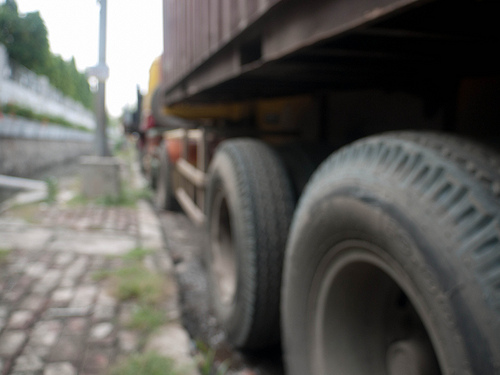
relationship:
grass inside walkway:
[0, 146, 196, 375] [3, 148, 199, 375]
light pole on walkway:
[92, 1, 107, 156] [5, 137, 200, 374]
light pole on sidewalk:
[92, 1, 107, 156] [0, 113, 185, 373]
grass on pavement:
[0, 146, 196, 375] [2, 143, 198, 373]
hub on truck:
[213, 208, 238, 308] [191, 136, 292, 356]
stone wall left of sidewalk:
[0, 59, 96, 174] [20, 165, 100, 297]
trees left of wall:
[0, 6, 94, 108] [11, 77, 102, 180]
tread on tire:
[298, 133, 499, 232] [281, 135, 498, 369]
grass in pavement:
[110, 246, 175, 343] [0, 146, 247, 373]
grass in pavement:
[0, 146, 196, 375] [0, 146, 247, 373]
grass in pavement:
[0, 146, 196, 375] [2, 119, 212, 370]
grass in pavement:
[0, 146, 196, 375] [9, 125, 221, 373]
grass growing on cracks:
[0, 146, 196, 375] [48, 248, 88, 310]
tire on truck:
[281, 135, 498, 369] [160, 2, 496, 370]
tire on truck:
[199, 134, 298, 365] [160, 2, 496, 370]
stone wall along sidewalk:
[0, 59, 96, 174] [3, 139, 203, 374]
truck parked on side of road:
[160, 2, 496, 370] [125, 152, 297, 374]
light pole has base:
[92, 1, 107, 156] [72, 140, 133, 220]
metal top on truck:
[157, 2, 349, 112] [160, 2, 496, 370]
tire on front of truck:
[281, 135, 498, 369] [159, 7, 496, 137]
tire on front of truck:
[199, 134, 298, 365] [159, 7, 496, 137]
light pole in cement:
[92, 1, 115, 156] [2, 116, 195, 373]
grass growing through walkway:
[0, 146, 196, 375] [3, 148, 199, 375]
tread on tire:
[298, 116, 498, 283] [228, 122, 498, 334]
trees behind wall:
[5, 2, 97, 97] [0, 45, 98, 214]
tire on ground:
[199, 134, 298, 365] [2, 103, 240, 370]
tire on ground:
[281, 135, 498, 375] [2, 103, 240, 370]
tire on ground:
[281, 135, 498, 375] [0, 122, 224, 373]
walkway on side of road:
[3, 148, 178, 373] [157, 152, 259, 374]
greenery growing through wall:
[7, 102, 109, 137] [0, 60, 103, 214]